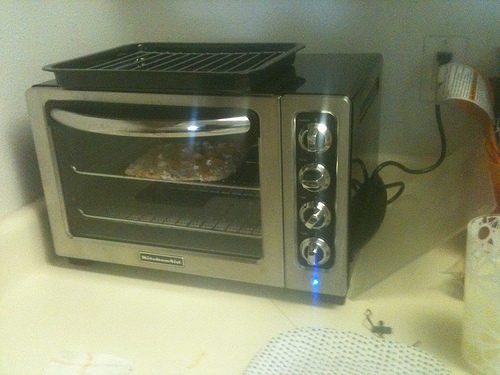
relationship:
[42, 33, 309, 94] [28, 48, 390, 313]
tray on top of oven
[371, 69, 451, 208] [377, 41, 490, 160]
cord plugged into wall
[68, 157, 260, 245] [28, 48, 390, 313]
racks in oven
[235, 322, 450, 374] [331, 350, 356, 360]
pot holder with dots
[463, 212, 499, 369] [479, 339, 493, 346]
glass with liquid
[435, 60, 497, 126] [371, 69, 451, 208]
tag attached to cord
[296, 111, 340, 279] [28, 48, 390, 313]
knobs on oven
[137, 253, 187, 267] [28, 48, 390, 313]
logo on oven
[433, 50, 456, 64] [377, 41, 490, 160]
plug in wall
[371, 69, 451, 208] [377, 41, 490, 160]
cord on wall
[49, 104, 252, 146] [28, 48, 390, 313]
handle on oven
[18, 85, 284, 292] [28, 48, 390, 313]
door on oven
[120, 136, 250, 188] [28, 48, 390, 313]
pizza in oven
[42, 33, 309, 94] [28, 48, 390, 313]
tray on oven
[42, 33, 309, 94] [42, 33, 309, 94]
tray with tray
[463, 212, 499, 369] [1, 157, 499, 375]
glass on counter top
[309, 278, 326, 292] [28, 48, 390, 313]
light on front of oven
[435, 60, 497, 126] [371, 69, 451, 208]
tag on cord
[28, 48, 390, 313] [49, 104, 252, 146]
oven has handle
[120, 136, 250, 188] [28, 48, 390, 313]
pizza inside oven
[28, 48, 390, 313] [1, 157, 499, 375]
oven on counter top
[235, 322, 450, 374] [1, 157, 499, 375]
pot holder on counter top